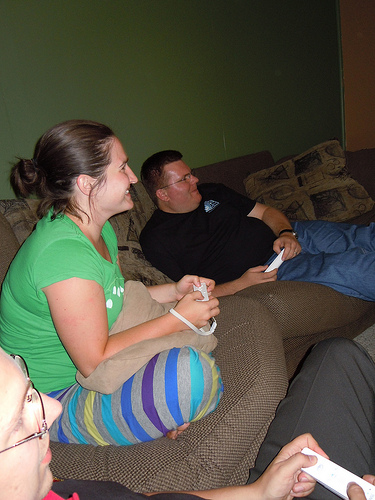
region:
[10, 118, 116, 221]
long dark hair in a bun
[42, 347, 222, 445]
striped pajama pants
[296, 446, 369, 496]
wii game controller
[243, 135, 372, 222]
a big pillow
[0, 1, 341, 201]
green wall in the background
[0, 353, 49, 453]
glasses on a person's face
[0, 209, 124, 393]
a green t-shirt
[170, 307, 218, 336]
a wii controller strap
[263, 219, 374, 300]
wrinkled blue jeans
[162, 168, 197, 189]
glasses on the man's face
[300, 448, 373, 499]
a Wii hand game controller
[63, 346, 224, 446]
grey striped warm up pants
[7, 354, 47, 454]
wire rim eye glasses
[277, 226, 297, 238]
a wrist watch on the mans wrist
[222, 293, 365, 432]
a brown cloth sofa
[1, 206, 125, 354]
the girl is wearing a green t-shirt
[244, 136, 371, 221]
a beige and brown sofa pillow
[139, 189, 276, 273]
the man is wearing a black t-shirt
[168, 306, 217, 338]
a Wii game controller wrist strap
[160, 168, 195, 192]
the man is wearing wire rim eye glasses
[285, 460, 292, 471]
part of a finger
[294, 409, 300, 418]
part of a trouser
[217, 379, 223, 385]
edge of a knee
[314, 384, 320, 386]
part of a shoulder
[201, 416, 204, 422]
edge of a knee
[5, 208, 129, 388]
Green shirt on a woman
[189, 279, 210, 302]
Game controller in a woman's hands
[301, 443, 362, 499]
Game controller in a man's hands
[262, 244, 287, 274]
Game controller in a man's hands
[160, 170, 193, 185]
Eyeglasses on a man's face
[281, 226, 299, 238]
Watch on a man's wrist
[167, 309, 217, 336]
White strap for video controller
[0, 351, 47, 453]
Glasses on a man's face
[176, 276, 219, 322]
Hands gripping a game controller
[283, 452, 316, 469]
A thumb pressed on a game controller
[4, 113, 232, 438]
Woman smiling in striped pants.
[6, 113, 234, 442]
Woman in green shirt holding Wii controller.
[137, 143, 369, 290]
Man in black shirt with a black watch.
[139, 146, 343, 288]
Man in black shirt and jeans wearing glasses.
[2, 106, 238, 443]
Woman with pony tail playing Wii.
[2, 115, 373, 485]
People holding Wii remotes on brown couch.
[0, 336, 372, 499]
Person with glasses wearing gray pants.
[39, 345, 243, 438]
Foot under striped gray pants.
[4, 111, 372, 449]
Woman and man sitting on brown patterned couch.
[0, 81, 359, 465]
Green wall behind family on couch.